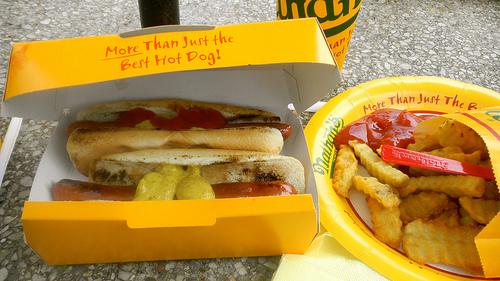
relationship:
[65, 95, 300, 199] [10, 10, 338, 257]
dogs in carton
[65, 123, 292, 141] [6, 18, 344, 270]
dogs in box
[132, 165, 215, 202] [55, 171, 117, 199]
mustard on dog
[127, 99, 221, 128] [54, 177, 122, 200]
ketchup on dog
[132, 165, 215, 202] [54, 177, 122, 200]
mustard on dog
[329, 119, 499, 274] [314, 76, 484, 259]
crinkle fries on plate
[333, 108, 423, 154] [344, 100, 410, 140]
ketchup on plate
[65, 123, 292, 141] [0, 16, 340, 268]
dogs in box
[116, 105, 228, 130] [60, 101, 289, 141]
ketchup on hot dog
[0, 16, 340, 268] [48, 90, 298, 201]
box for hot dog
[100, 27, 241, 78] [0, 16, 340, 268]
phrase on box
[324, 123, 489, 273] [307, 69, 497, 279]
crinkle fries on plate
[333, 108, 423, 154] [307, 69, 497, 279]
ketchup on plate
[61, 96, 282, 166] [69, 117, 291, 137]
bun for hot dog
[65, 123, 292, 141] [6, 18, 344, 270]
dogs inside box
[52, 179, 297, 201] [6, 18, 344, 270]
dog inside box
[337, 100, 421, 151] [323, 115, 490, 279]
ketchup next to fries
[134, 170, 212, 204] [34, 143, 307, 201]
mustard on hot dog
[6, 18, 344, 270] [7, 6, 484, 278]
box on top of table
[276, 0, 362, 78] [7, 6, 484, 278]
drink cup on top of table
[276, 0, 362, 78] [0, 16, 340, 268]
drink cup next to box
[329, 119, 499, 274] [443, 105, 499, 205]
crinkle fries inside bag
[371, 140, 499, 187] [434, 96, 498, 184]
utensil inside bag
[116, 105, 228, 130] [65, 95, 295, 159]
ketchup on top of hot dog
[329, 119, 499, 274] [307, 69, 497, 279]
crinkle fries on plate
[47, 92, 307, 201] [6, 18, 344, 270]
food in box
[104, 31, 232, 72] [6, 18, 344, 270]
phrase on box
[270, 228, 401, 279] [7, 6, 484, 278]
napkin on table